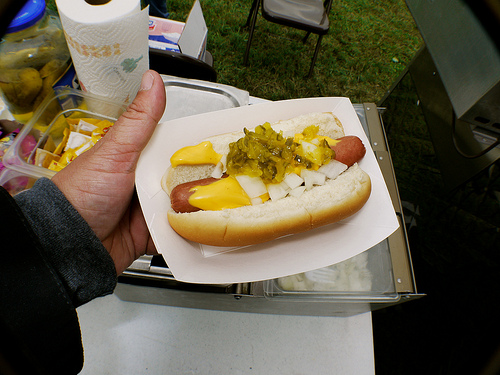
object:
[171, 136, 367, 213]
hot dog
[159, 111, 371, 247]
bun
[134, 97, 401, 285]
plate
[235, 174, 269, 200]
onion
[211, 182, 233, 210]
mustard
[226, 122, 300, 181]
relish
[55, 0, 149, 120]
paper towel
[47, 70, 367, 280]
hand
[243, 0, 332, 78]
chair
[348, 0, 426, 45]
lawn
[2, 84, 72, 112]
pickle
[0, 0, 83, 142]
jar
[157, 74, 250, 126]
tray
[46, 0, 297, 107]
grass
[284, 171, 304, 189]
onion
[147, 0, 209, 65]
box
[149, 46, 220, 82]
chair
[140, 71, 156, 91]
nail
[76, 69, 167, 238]
thumb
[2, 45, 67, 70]
pickle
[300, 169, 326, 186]
onion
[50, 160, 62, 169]
mustard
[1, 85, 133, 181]
bin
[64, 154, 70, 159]
mustard